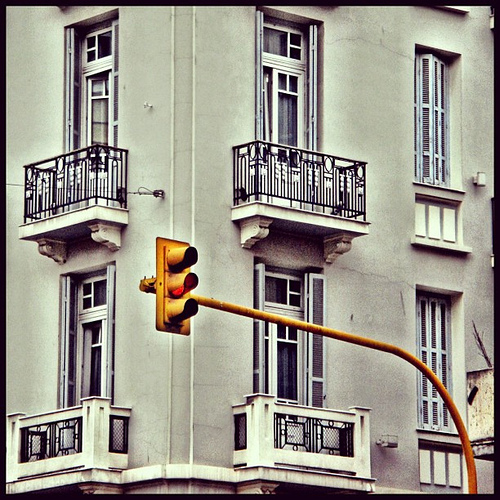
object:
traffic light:
[134, 234, 486, 496]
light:
[464, 164, 498, 197]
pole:
[135, 276, 473, 500]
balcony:
[218, 384, 390, 499]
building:
[6, 7, 491, 494]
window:
[411, 276, 475, 439]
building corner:
[153, 6, 211, 500]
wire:
[3, 178, 167, 201]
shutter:
[413, 48, 436, 185]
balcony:
[222, 120, 376, 275]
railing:
[234, 154, 362, 209]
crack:
[327, 259, 416, 295]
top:
[163, 242, 203, 273]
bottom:
[157, 292, 202, 333]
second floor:
[4, 5, 499, 278]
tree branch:
[465, 313, 496, 372]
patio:
[458, 355, 500, 455]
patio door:
[76, 64, 122, 183]